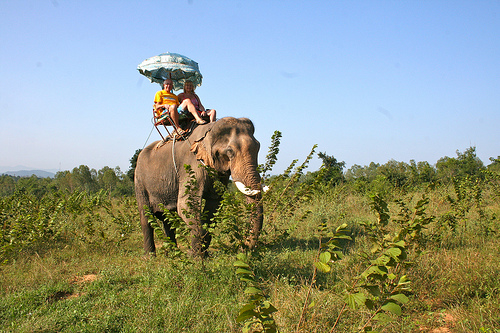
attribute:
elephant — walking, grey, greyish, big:
[134, 116, 270, 263]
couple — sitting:
[156, 78, 217, 136]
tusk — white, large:
[234, 181, 260, 196]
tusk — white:
[262, 183, 269, 193]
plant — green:
[351, 208, 431, 319]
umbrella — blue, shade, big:
[136, 53, 203, 90]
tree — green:
[436, 158, 464, 184]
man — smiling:
[155, 79, 203, 131]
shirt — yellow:
[155, 90, 179, 107]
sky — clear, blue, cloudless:
[6, 3, 495, 179]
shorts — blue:
[163, 106, 184, 117]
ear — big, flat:
[191, 128, 216, 169]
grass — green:
[3, 265, 249, 331]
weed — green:
[235, 251, 275, 329]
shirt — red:
[181, 94, 200, 109]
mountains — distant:
[9, 169, 70, 182]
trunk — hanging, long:
[228, 156, 263, 250]